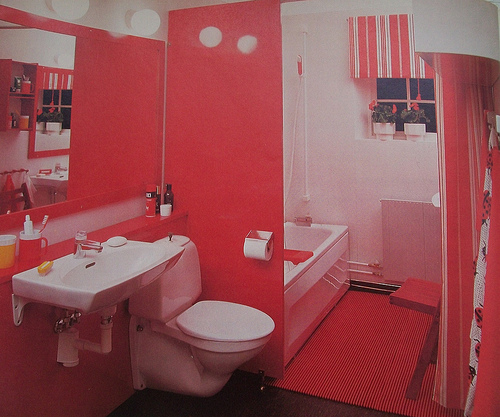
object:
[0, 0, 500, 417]
toilet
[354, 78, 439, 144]
pot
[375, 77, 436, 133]
window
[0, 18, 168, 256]
mirror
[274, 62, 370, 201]
wall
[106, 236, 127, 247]
soap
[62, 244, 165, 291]
basin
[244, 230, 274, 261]
paper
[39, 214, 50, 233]
brush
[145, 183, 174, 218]
creme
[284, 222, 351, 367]
bathtub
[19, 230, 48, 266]
cup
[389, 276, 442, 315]
rug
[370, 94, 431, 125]
plant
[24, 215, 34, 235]
tube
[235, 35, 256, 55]
decor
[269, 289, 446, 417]
mat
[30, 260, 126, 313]
porcelain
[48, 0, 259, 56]
lighting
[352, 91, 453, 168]
window sill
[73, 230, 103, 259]
faucet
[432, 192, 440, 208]
knob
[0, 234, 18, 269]
container